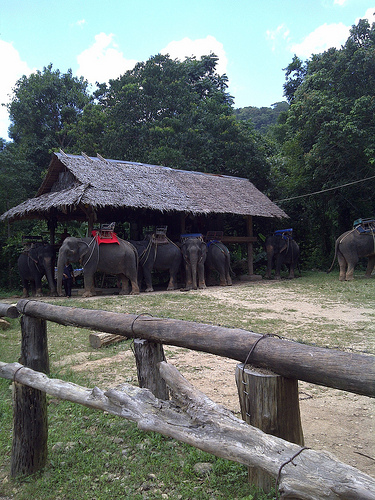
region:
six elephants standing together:
[14, 221, 309, 298]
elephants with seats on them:
[17, 224, 302, 287]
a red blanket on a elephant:
[77, 219, 123, 276]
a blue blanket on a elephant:
[182, 225, 208, 252]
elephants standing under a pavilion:
[23, 177, 291, 292]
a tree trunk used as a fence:
[5, 344, 362, 450]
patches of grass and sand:
[207, 286, 346, 328]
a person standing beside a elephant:
[50, 254, 77, 294]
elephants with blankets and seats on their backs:
[53, 213, 236, 259]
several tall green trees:
[39, 72, 366, 150]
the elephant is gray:
[50, 230, 146, 296]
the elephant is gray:
[130, 231, 180, 287]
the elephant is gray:
[307, 217, 371, 295]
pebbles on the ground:
[89, 453, 139, 485]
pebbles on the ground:
[101, 421, 203, 498]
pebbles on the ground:
[121, 446, 196, 491]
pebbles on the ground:
[111, 452, 172, 495]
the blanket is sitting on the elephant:
[99, 233, 123, 258]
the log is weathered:
[132, 361, 240, 448]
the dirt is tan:
[278, 295, 311, 315]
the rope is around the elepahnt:
[85, 239, 97, 257]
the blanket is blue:
[207, 239, 225, 248]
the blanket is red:
[100, 237, 122, 248]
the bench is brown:
[201, 229, 227, 244]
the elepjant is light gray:
[102, 251, 121, 266]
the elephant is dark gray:
[278, 244, 293, 253]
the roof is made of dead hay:
[162, 179, 187, 195]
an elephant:
[56, 243, 150, 287]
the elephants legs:
[114, 270, 141, 295]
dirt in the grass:
[270, 286, 331, 323]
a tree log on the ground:
[150, 383, 272, 473]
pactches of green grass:
[160, 295, 217, 315]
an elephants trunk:
[185, 254, 201, 286]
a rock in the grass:
[188, 461, 216, 478]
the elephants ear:
[78, 241, 88, 255]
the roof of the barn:
[74, 175, 250, 206]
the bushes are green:
[256, 138, 339, 172]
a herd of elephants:
[19, 220, 373, 306]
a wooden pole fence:
[19, 316, 295, 408]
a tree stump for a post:
[11, 296, 64, 478]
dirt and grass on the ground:
[208, 275, 329, 361]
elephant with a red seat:
[56, 225, 140, 299]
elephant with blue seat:
[184, 228, 208, 290]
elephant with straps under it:
[142, 239, 162, 274]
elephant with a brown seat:
[141, 225, 176, 256]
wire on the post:
[236, 327, 284, 416]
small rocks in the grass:
[121, 457, 220, 493]